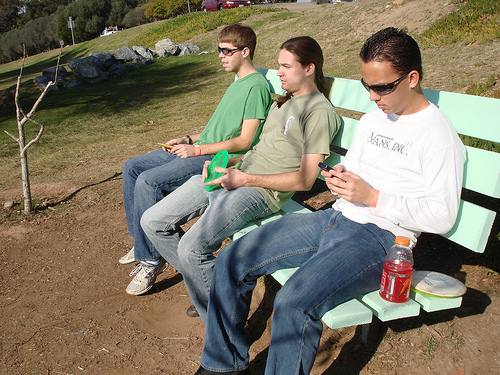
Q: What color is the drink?
A: Red.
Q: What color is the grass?
A: Green.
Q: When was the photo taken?
A: During the day.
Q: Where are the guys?
A: In a park.